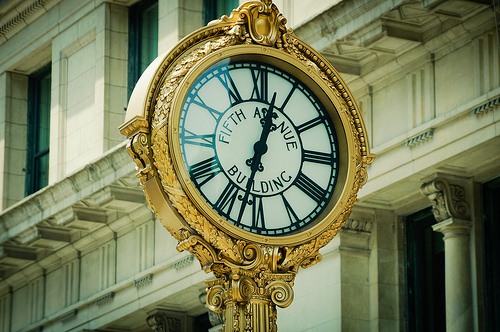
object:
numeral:
[215, 70, 244, 106]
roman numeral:
[280, 192, 301, 225]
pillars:
[417, 172, 484, 332]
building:
[0, 0, 105, 296]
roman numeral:
[189, 156, 222, 188]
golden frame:
[118, 1, 375, 313]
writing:
[218, 106, 298, 193]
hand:
[236, 91, 279, 225]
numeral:
[192, 92, 223, 122]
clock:
[118, 0, 376, 332]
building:
[0, 0, 500, 332]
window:
[23, 60, 47, 197]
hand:
[236, 152, 264, 224]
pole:
[205, 265, 295, 331]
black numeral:
[303, 149, 331, 165]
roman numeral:
[302, 148, 331, 167]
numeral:
[292, 171, 326, 204]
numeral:
[184, 128, 214, 148]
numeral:
[251, 194, 266, 229]